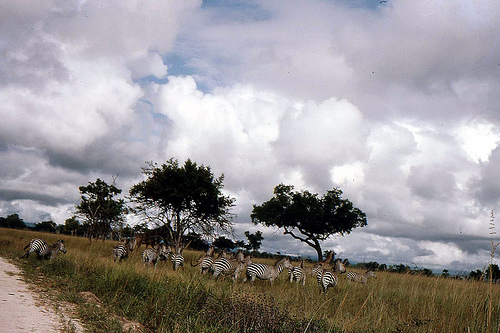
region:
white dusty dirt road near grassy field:
[0, 245, 172, 332]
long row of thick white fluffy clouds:
[1, 51, 498, 251]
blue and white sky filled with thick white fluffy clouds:
[0, 0, 499, 275]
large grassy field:
[0, 224, 498, 331]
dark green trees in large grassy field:
[71, 153, 371, 288]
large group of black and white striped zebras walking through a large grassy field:
[18, 232, 385, 299]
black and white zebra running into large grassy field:
[18, 235, 74, 263]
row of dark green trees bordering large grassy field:
[1, 210, 498, 287]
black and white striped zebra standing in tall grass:
[242, 255, 297, 290]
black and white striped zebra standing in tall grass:
[343, 266, 380, 291]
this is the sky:
[25, 16, 464, 148]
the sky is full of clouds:
[23, 16, 423, 133]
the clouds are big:
[21, 17, 449, 172]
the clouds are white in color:
[221, 38, 369, 143]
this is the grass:
[127, 273, 202, 317]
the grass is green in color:
[124, 279, 185, 319]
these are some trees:
[66, 162, 361, 242]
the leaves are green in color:
[186, 178, 211, 198]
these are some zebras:
[96, 228, 384, 286]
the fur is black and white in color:
[251, 262, 269, 275]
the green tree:
[247, 180, 372, 240]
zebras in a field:
[222, 248, 344, 290]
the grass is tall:
[212, 293, 368, 323]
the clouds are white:
[285, 108, 430, 163]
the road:
[0, 280, 44, 330]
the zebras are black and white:
[205, 256, 252, 287]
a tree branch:
[287, 223, 320, 247]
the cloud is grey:
[13, 110, 123, 167]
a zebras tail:
[19, 237, 31, 249]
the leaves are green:
[138, 164, 227, 206]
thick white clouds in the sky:
[1, 2, 499, 267]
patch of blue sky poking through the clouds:
[159, 49, 199, 91]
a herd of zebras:
[19, 215, 364, 295]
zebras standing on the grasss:
[15, 225, 385, 299]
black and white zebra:
[23, 231, 74, 261]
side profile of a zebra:
[246, 247, 293, 289]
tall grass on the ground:
[4, 224, 495, 328]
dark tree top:
[251, 179, 366, 243]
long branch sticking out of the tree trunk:
[282, 231, 319, 253]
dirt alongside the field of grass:
[1, 257, 57, 332]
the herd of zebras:
[19, 238, 376, 288]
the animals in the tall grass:
[17, 236, 377, 296]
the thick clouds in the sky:
[0, 0, 499, 268]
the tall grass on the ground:
[1, 226, 499, 331]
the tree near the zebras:
[250, 181, 368, 266]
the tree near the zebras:
[125, 156, 234, 252]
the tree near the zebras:
[73, 174, 125, 242]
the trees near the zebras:
[76, 156, 369, 264]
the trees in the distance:
[1, 212, 498, 281]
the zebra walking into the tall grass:
[19, 238, 68, 263]